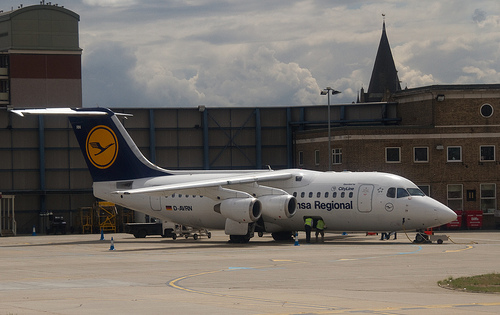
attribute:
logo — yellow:
[84, 124, 119, 170]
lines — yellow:
[167, 239, 498, 313]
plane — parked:
[6, 102, 460, 245]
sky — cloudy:
[1, 1, 500, 108]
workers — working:
[304, 216, 325, 243]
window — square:
[382, 143, 404, 166]